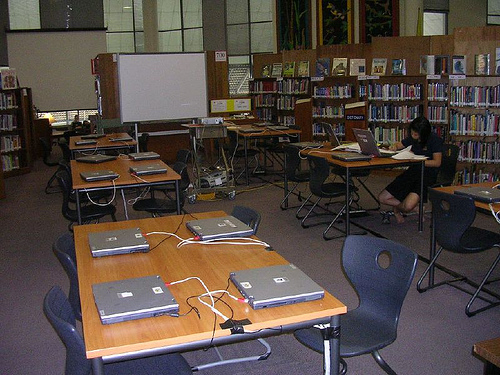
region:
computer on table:
[89, 225, 149, 257]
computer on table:
[233, 262, 328, 305]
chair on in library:
[343, 225, 402, 373]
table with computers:
[73, 202, 329, 356]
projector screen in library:
[8, 33, 113, 111]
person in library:
[387, 118, 442, 213]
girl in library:
[389, 115, 438, 216]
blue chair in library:
[334, 232, 429, 372]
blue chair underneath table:
[33, 292, 96, 374]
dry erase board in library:
[121, 53, 208, 121]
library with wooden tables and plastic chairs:
[10, 5, 490, 367]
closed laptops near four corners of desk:
[75, 205, 345, 360]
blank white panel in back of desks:
[110, 45, 210, 125]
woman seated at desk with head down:
[365, 110, 450, 220]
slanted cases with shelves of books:
[245, 45, 490, 195]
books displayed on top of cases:
[265, 50, 495, 80]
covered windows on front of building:
[5, 0, 275, 50]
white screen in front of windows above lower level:
[1, 25, 101, 137]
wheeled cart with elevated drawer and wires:
[182, 117, 232, 198]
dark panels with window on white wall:
[276, 1, 496, 46]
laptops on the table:
[52, 208, 361, 363]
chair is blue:
[311, 229, 428, 374]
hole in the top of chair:
[362, 241, 407, 276]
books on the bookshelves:
[274, 55, 498, 168]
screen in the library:
[116, 39, 220, 136]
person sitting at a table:
[379, 100, 472, 240]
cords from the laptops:
[171, 272, 254, 347]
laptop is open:
[353, 121, 404, 168]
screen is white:
[117, 42, 224, 127]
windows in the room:
[104, 1, 280, 53]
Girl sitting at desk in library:
[375, 115, 442, 221]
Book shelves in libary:
[251, 52, 494, 119]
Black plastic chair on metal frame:
[337, 236, 418, 365]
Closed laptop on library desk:
[223, 256, 323, 310]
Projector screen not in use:
[19, 26, 107, 108]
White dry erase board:
[117, 48, 209, 125]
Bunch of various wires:
[184, 150, 232, 200]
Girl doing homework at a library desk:
[372, 115, 448, 222]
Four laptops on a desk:
[88, 212, 303, 330]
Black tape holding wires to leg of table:
[317, 321, 342, 343]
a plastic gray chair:
[304, 235, 424, 370]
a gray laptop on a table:
[228, 255, 321, 312]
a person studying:
[376, 111, 453, 235]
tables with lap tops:
[0, 105, 499, 362]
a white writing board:
[120, 56, 212, 122]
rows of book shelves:
[253, 77, 498, 134]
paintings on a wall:
[281, 2, 391, 42]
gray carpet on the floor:
[1, 160, 58, 360]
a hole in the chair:
[337, 231, 416, 308]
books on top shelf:
[443, 53, 496, 74]